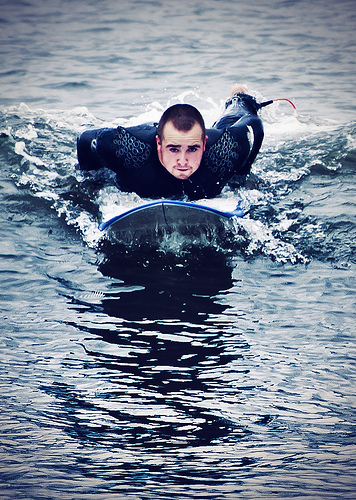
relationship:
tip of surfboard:
[147, 194, 187, 214] [99, 195, 232, 251]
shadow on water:
[103, 244, 239, 419] [3, 1, 355, 498]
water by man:
[3, 1, 355, 498] [74, 90, 264, 205]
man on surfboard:
[74, 90, 264, 205] [99, 195, 232, 251]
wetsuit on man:
[78, 90, 263, 199] [74, 90, 264, 205]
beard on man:
[169, 164, 197, 180] [74, 90, 264, 205]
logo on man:
[88, 135, 99, 145] [74, 90, 264, 205]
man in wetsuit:
[74, 90, 264, 205] [78, 90, 263, 199]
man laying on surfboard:
[74, 90, 264, 205] [99, 195, 232, 251]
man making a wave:
[74, 90, 264, 205] [9, 97, 111, 241]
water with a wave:
[3, 1, 355, 498] [9, 97, 111, 241]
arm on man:
[71, 123, 113, 187] [74, 90, 264, 205]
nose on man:
[177, 151, 188, 167] [74, 90, 264, 205]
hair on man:
[156, 103, 207, 145] [74, 90, 264, 205]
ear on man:
[154, 132, 164, 157] [74, 90, 264, 205]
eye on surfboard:
[186, 145, 198, 155] [99, 195, 232, 251]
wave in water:
[9, 97, 111, 241] [3, 1, 355, 498]